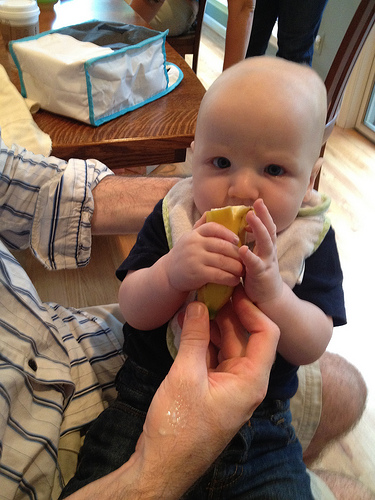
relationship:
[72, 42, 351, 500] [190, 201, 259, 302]
child has a banana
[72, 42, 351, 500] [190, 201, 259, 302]
child holding banana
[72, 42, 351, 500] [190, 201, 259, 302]
child eating a banana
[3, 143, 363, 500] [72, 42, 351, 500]
man holding child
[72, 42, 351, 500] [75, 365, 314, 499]
child wearing jeans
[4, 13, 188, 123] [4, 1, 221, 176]
bag on table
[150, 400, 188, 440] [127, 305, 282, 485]
moisture on hand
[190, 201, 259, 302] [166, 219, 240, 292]
banana in hand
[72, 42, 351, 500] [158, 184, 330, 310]
child wearing bib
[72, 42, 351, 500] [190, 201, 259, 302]
child eating banana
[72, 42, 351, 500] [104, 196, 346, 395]
child wearing shirt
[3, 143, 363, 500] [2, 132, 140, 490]
man wearing shirt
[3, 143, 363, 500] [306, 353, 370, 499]
man with legs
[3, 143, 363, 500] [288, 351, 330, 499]
man wearing shorts